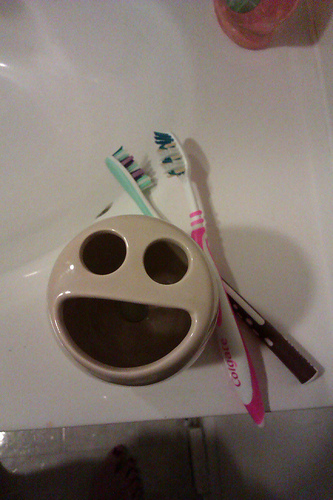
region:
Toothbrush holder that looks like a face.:
[41, 208, 220, 383]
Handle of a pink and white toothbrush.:
[215, 312, 267, 432]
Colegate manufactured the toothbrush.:
[221, 319, 247, 405]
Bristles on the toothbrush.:
[150, 119, 189, 192]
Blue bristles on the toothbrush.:
[147, 129, 170, 149]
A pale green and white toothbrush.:
[103, 131, 153, 209]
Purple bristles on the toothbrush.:
[119, 150, 147, 182]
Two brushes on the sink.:
[93, 112, 213, 222]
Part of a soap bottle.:
[206, 7, 314, 51]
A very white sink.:
[224, 43, 319, 203]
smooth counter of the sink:
[3, 211, 329, 407]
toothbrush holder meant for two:
[45, 211, 219, 387]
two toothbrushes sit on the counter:
[104, 131, 319, 427]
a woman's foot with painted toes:
[85, 442, 143, 498]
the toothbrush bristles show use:
[104, 129, 191, 195]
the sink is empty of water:
[0, 1, 180, 256]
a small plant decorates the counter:
[212, 1, 302, 48]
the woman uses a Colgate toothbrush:
[150, 126, 263, 422]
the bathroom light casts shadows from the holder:
[44, 215, 311, 387]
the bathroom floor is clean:
[0, 423, 204, 499]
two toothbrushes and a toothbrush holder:
[27, 129, 331, 439]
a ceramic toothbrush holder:
[39, 209, 227, 389]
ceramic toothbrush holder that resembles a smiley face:
[37, 204, 240, 399]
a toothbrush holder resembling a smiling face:
[39, 210, 231, 396]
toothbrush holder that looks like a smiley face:
[41, 210, 225, 394]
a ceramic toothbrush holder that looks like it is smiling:
[37, 206, 225, 393]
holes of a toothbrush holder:
[72, 220, 200, 286]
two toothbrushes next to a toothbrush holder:
[28, 126, 329, 430]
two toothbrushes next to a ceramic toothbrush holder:
[24, 121, 326, 453]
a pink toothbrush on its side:
[149, 125, 278, 432]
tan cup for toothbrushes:
[62, 178, 208, 362]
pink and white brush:
[179, 156, 265, 441]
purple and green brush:
[120, 162, 314, 387]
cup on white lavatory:
[64, 225, 218, 405]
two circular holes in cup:
[73, 235, 208, 314]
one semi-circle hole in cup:
[40, 299, 202, 367]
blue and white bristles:
[152, 129, 180, 180]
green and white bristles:
[94, 148, 172, 216]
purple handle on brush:
[232, 291, 297, 376]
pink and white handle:
[200, 275, 270, 447]